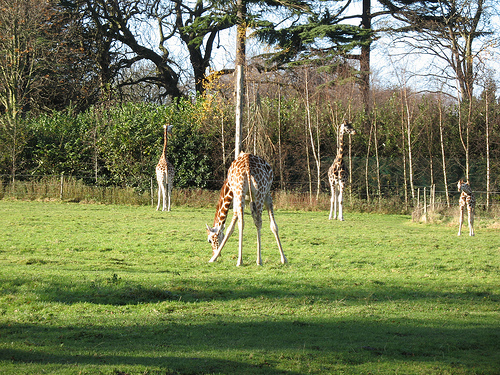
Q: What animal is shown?
A: Giraffe.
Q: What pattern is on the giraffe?
A: Spots.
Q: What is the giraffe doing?
A: Grazing.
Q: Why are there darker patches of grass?
A: The shadows.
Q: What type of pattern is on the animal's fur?
A: Spots.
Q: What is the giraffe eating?
A: Grass.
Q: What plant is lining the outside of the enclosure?
A: Trees.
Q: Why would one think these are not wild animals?
A: The are fenced in.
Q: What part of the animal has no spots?
A: The legs.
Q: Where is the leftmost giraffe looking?
A: To the trees.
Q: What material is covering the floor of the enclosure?
A: Grass.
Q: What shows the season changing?
A: The leaves.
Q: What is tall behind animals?
A: Trees.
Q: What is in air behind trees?
A: Blue sky.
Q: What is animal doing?
A: Grazing on grass.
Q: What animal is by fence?
A: Giraffes.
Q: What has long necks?
A: Giraffes.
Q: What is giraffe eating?
A: Grass.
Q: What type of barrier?
A: Fence on wooden poles.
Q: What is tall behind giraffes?
A: Trees.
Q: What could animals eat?
A: Green grass.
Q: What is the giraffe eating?
A: Grass.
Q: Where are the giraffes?
A: In the park.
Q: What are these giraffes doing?
A: Eating.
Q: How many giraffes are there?
A: Four.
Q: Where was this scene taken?
A: The zoo.